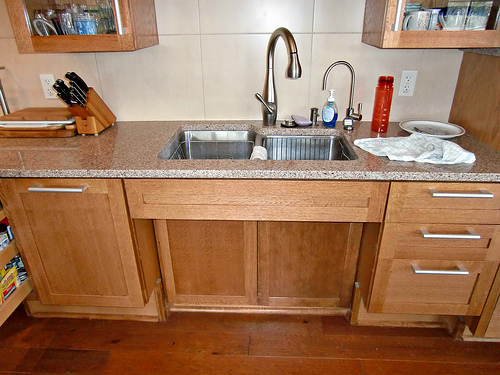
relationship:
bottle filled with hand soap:
[320, 87, 338, 127] [318, 110, 338, 123]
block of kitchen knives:
[68, 87, 117, 137] [47, 72, 83, 105]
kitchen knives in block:
[53, 71, 91, 107] [71, 89, 118, 138]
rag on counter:
[354, 133, 477, 164] [12, 119, 477, 174]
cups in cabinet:
[403, 5, 493, 26] [361, 0, 499, 49]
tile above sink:
[161, 26, 243, 86] [151, 17, 361, 163]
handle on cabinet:
[428, 189, 494, 198] [8, 155, 139, 299]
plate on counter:
[397, 116, 465, 143] [3, 119, 498, 180]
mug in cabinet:
[392, 5, 428, 39] [358, 2, 498, 49]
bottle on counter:
[368, 75, 394, 132] [3, 119, 498, 180]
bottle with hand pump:
[322, 89, 339, 128] [327, 87, 337, 102]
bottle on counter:
[322, 89, 339, 128] [3, 119, 498, 180]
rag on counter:
[354, 133, 477, 164] [3, 119, 498, 180]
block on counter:
[68, 87, 117, 137] [3, 119, 498, 180]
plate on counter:
[399, 118, 467, 139] [25, 96, 423, 208]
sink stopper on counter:
[276, 115, 301, 130] [3, 119, 498, 180]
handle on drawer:
[428, 189, 491, 199] [383, 180, 498, 225]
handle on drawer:
[420, 229, 481, 240] [379, 222, 496, 263]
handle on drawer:
[411, 263, 470, 275] [368, 260, 498, 317]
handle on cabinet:
[26, 180, 88, 194] [1, 176, 146, 310]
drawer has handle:
[366, 177, 484, 318] [430, 186, 495, 201]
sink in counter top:
[158, 129, 356, 162] [0, 122, 498, 182]